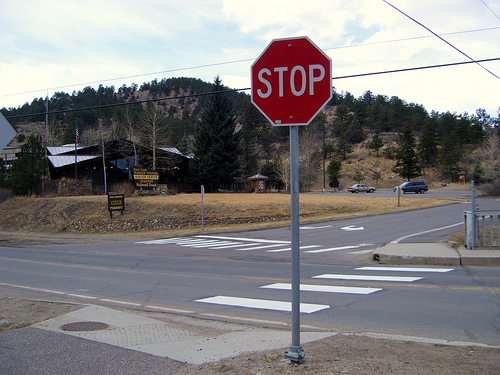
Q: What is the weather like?
A: It is cloudy.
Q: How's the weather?
A: It is cloudy.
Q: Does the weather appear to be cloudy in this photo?
A: Yes, it is cloudy.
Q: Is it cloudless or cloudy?
A: It is cloudy.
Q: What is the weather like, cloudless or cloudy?
A: It is cloudy.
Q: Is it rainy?
A: No, it is cloudy.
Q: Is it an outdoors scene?
A: Yes, it is outdoors.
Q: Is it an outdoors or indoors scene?
A: It is outdoors.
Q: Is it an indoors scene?
A: No, it is outdoors.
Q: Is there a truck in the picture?
A: No, there are no trucks.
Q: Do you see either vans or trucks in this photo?
A: No, there are no trucks or vans.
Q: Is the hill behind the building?
A: Yes, the hill is behind the building.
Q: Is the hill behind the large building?
A: Yes, the hill is behind the building.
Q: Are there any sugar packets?
A: No, there are no sugar packets.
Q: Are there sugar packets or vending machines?
A: No, there are no sugar packets or vending machines.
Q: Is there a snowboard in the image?
A: No, there are no snowboards.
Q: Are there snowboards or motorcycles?
A: No, there are no snowboards or motorcycles.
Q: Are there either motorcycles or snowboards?
A: No, there are no snowboards or motorcycles.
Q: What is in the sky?
A: The clouds are in the sky.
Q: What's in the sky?
A: The clouds are in the sky.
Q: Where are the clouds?
A: The clouds are in the sky.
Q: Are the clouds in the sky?
A: Yes, the clouds are in the sky.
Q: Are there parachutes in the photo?
A: No, there are no parachutes.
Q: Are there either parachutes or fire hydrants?
A: No, there are no parachutes or fire hydrants.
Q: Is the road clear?
A: Yes, the road is clear.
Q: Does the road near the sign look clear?
A: Yes, the road is clear.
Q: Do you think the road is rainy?
A: No, the road is clear.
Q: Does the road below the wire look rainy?
A: No, the road is clear.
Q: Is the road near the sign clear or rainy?
A: The road is clear.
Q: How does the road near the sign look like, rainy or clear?
A: The road is clear.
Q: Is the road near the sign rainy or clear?
A: The road is clear.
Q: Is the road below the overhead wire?
A: Yes, the road is below the wire.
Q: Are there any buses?
A: No, there are no buses.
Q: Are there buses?
A: No, there are no buses.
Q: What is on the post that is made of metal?
A: The sign is on the post.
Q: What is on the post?
A: The sign is on the post.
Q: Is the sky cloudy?
A: Yes, the sky is cloudy.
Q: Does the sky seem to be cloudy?
A: Yes, the sky is cloudy.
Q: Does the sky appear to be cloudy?
A: Yes, the sky is cloudy.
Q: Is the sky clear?
A: No, the sky is cloudy.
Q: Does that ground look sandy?
A: Yes, the ground is sandy.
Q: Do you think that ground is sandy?
A: Yes, the ground is sandy.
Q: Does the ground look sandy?
A: Yes, the ground is sandy.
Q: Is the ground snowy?
A: No, the ground is sandy.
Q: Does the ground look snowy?
A: No, the ground is sandy.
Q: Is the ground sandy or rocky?
A: The ground is sandy.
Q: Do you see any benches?
A: No, there are no benches.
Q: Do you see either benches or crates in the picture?
A: No, there are no benches or crates.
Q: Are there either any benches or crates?
A: No, there are no benches or crates.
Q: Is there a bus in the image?
A: No, there are no buses.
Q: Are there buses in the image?
A: No, there are no buses.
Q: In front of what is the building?
A: The building is in front of the hill.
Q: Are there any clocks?
A: No, there are no clocks.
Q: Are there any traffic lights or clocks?
A: No, there are no clocks or traffic lights.